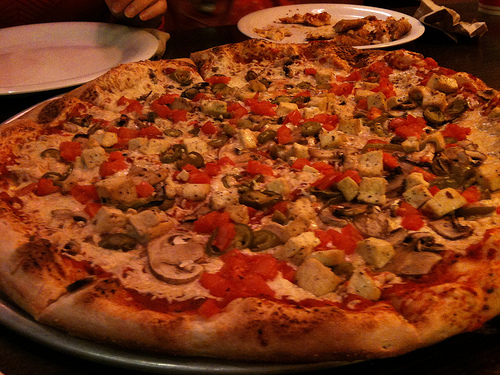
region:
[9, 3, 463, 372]
large pizza on the table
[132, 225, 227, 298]
mushrooms on the pizza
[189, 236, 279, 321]
tomatoes on the pizza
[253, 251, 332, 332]
piece of chicken on the pizza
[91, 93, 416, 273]
many toppings on the pizza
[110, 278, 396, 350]
crust on the pizza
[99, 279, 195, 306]
cheese on top of pizza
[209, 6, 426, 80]
plate full of pizza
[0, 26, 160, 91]
white empty plate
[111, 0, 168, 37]
persons hand and nails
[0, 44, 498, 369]
a pizza on a pan.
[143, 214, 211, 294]
a mushroom on a pizza.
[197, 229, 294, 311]
a section of sauce on a pizza.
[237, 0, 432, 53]
a white plate topped with food.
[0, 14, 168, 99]
a white paper plate.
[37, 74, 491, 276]
cheesy toppings on a pizza.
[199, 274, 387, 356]
a brown pizza crust.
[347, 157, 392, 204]
assorted pizza toppings.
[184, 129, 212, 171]
a section of cheese.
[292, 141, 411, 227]
an assortment of veggies.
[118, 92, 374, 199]
this is a pizza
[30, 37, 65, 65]
this is a plate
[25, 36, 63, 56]
the plate is white in color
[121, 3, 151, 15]
these are the fingers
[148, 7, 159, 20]
the skin is light in color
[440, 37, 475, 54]
this is a table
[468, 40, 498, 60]
the table is wooden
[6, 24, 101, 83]
the plate is round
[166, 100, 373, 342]
the pizza is brown in color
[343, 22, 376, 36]
this is a beef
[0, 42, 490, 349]
A large pizza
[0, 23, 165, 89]
an empty white plate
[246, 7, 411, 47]
A white plate with food on it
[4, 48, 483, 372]
a large, silver pizza pan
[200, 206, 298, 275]
jalapenos on the pizza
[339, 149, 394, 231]
zucchinis on the pizza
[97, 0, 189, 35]
A human hand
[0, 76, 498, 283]
cheese on the pizza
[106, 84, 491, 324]
the pizza is very big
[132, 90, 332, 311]
the pizza is very big